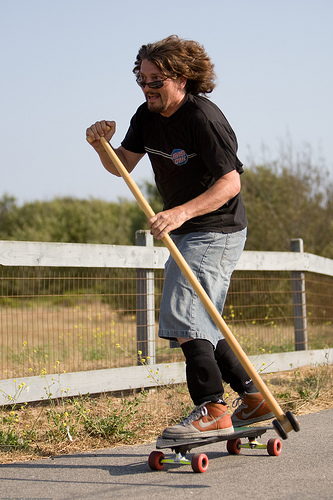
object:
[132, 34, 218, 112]
head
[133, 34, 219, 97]
hair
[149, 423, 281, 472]
skateboard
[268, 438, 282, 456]
wheel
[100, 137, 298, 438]
mallet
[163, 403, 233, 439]
shoe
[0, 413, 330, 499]
road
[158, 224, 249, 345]
shorts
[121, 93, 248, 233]
t-shirt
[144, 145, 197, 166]
logo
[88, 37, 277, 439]
man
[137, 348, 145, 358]
flower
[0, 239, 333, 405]
fence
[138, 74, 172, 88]
sunglasses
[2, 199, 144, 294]
shrub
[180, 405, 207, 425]
shoelace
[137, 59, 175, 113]
face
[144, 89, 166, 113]
goatee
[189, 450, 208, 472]
front wheel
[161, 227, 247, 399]
leg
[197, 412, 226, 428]
logo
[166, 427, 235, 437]
sole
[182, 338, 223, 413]
pads